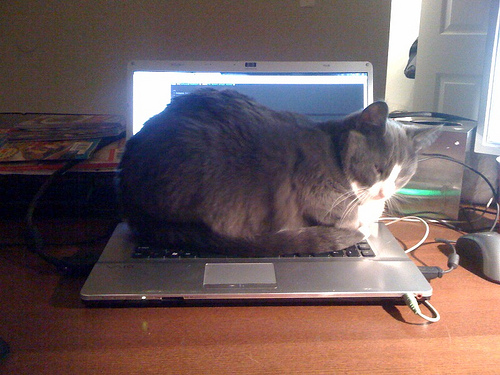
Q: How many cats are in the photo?
A: One.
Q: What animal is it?
A: Cat.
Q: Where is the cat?
A: On the computer.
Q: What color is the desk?
A: Brown.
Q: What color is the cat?
A: Gray and white.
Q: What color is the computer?
A: Silver.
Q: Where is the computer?
A: Desk.